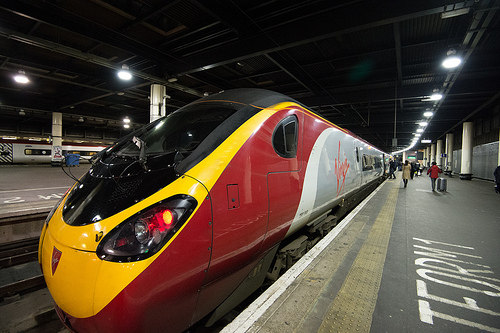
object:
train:
[32, 85, 396, 332]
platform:
[220, 169, 499, 332]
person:
[426, 157, 442, 196]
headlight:
[93, 192, 198, 262]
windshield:
[86, 99, 244, 182]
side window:
[270, 112, 299, 159]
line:
[317, 169, 404, 330]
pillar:
[458, 119, 473, 183]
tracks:
[0, 237, 49, 333]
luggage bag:
[434, 175, 449, 194]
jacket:
[426, 164, 443, 180]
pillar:
[443, 131, 455, 176]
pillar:
[433, 136, 444, 170]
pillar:
[429, 142, 437, 170]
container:
[61, 150, 84, 166]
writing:
[407, 235, 499, 332]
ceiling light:
[438, 54, 463, 71]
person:
[398, 159, 414, 189]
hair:
[401, 159, 410, 166]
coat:
[399, 162, 412, 181]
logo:
[48, 243, 65, 276]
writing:
[331, 139, 352, 197]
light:
[427, 90, 445, 103]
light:
[422, 110, 437, 121]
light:
[415, 120, 431, 129]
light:
[416, 127, 424, 133]